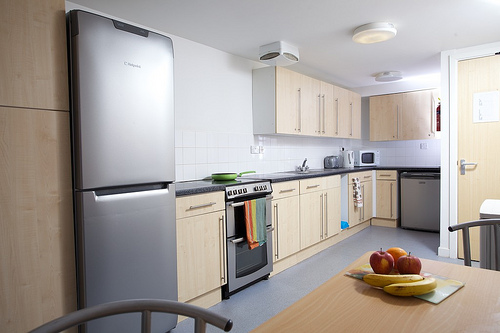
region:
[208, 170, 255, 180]
A green cooking skillet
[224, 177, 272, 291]
A stainless stove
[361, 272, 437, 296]
Two yellow bananas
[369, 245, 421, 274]
Two apples and an orange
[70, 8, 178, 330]
A tall modern refrigerator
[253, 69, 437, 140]
Kitchen cabinets with handles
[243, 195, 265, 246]
A multicolored towel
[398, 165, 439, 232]
An under the counter dishwasher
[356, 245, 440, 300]
Three kinds of fruit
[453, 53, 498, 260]
A door with a silver handle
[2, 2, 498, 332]
This is a kitchen scene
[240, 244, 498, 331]
A kitchen table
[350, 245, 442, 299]
Fruit is laying on the table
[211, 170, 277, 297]
This is a kitchen stove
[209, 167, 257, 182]
A frying pan is on the stove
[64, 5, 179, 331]
A refrigerator freezer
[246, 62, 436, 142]
Kitchen cabinets are on the wall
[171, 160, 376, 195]
A kitchen counter top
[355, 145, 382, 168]
A microwave is on the counter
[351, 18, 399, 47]
A light is on the ceiling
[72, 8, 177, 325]
stainless steel refrigerator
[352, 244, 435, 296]
bananas and apples on the table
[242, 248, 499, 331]
wooden table with fruit on it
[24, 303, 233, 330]
chair in front of the table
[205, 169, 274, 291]
stainless steel oven and stove top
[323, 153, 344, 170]
toaster on the counter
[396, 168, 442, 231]
stainless steel dishwasher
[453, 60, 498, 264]
light brown door leading to other area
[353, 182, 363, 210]
towel hangin on the drawer handle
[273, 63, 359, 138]
light brown wooden cabinets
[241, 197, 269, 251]
multi-colored towel on oven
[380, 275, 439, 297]
yellow banana on table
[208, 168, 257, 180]
green frying pan on stove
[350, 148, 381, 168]
white microwave on counter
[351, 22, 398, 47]
white light fixture on ceiling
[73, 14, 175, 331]
large stainless steel refrigerator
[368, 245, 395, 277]
red apple on table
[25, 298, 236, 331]
silver chair near table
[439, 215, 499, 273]
silver chair near table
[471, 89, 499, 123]
white sign on wood door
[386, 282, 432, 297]
A banana on a fruit tray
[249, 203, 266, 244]
A striped dish towel hanging on an oven door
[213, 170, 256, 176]
A green skillet on a stove top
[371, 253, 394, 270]
A red apple on a plate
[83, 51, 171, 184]
A stainless steel refrigerator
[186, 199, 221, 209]
A long straight drawer handle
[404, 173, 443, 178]
The black handle on a dishwasher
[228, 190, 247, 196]
Burner knobs on a stove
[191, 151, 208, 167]
Square white tiles on a kitchen wall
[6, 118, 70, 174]
Pale wooden cabinet door